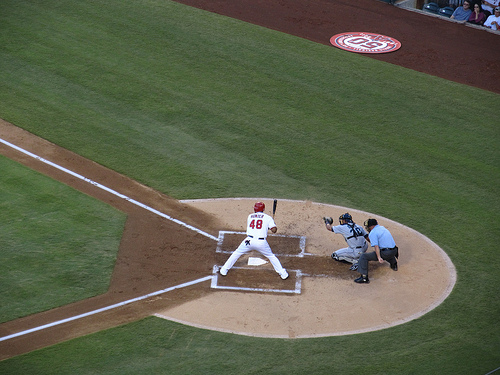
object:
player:
[221, 200, 288, 281]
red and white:
[250, 215, 273, 235]